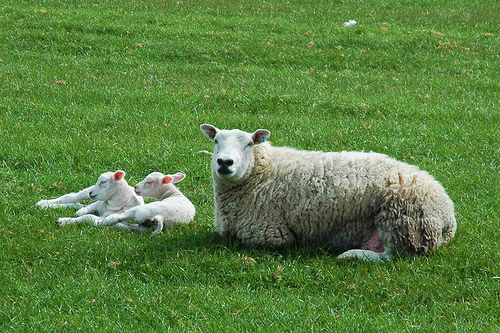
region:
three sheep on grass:
[61, 127, 431, 269]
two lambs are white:
[51, 171, 175, 230]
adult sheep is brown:
[219, 55, 491, 276]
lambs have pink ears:
[104, 161, 204, 193]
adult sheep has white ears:
[202, 104, 271, 152]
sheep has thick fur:
[215, 114, 439, 254]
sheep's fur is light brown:
[245, 146, 428, 242]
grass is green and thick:
[70, 0, 282, 110]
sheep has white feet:
[338, 227, 393, 285]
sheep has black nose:
[217, 162, 242, 184]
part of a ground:
[263, 15, 302, 67]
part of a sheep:
[318, 203, 338, 237]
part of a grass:
[201, 292, 236, 332]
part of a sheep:
[311, 201, 343, 251]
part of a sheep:
[214, 228, 278, 305]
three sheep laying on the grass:
[38, 105, 457, 285]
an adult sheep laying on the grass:
[190, 104, 462, 268]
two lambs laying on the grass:
[55, 148, 192, 252]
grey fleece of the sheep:
[260, 153, 431, 229]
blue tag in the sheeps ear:
[256, 131, 273, 146]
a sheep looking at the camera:
[192, 105, 452, 282]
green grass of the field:
[163, 38, 309, 101]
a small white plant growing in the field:
[333, 14, 365, 35]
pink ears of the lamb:
[159, 170, 186, 188]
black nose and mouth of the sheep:
[212, 156, 237, 180]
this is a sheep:
[203, 122, 455, 262]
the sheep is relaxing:
[199, 111, 454, 268]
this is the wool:
[296, 166, 361, 210]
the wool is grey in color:
[271, 163, 348, 208]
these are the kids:
[70, 160, 181, 234]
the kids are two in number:
[68, 152, 187, 232]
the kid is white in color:
[163, 191, 186, 209]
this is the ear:
[250, 122, 273, 142]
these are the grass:
[167, 264, 252, 329]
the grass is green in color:
[257, 267, 318, 330]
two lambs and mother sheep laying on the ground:
[36, 112, 457, 274]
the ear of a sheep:
[250, 122, 270, 145]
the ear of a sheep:
[196, 118, 217, 139]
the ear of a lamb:
[110, 165, 126, 189]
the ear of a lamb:
[158, 173, 175, 188]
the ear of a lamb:
[173, 168, 188, 184]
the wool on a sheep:
[287, 169, 327, 206]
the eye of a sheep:
[243, 138, 258, 153]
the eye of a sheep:
[210, 136, 220, 150]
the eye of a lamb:
[143, 177, 154, 188]